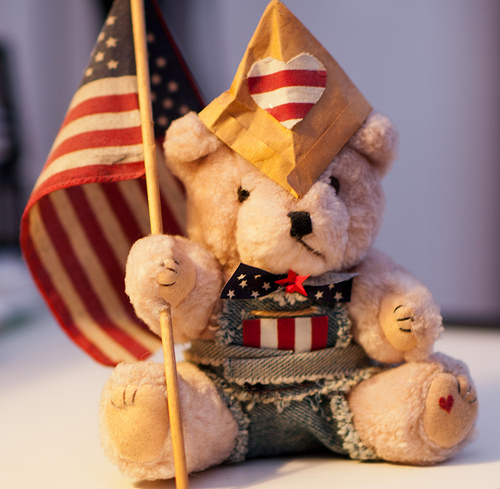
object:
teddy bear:
[102, 0, 475, 482]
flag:
[18, 0, 215, 489]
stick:
[129, 0, 191, 489]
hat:
[197, 0, 375, 200]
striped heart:
[249, 52, 326, 133]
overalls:
[188, 254, 378, 463]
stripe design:
[242, 315, 327, 349]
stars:
[238, 280, 249, 289]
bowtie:
[220, 262, 352, 303]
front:
[208, 269, 364, 420]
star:
[275, 269, 309, 296]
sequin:
[275, 268, 310, 295]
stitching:
[130, 391, 138, 402]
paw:
[104, 382, 168, 461]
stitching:
[293, 239, 326, 262]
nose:
[289, 210, 313, 240]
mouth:
[266, 241, 329, 272]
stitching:
[239, 193, 249, 204]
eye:
[236, 183, 249, 203]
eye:
[328, 172, 342, 196]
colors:
[239, 3, 336, 355]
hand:
[137, 234, 179, 300]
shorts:
[188, 344, 405, 466]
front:
[112, 377, 165, 463]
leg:
[335, 351, 470, 463]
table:
[0, 255, 500, 488]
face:
[189, 138, 383, 274]